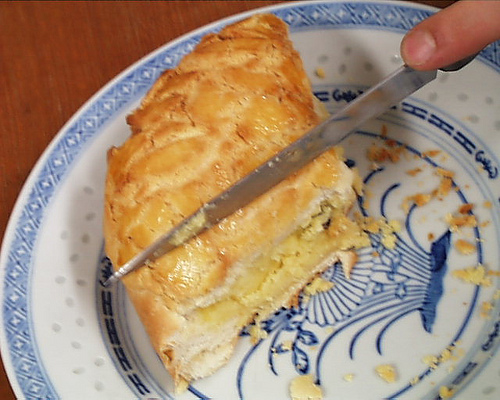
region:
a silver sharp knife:
[107, 49, 441, 294]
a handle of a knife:
[436, 41, 482, 78]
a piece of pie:
[98, 27, 373, 397]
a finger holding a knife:
[403, 2, 498, 74]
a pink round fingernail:
[400, 28, 434, 61]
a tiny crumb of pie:
[372, 361, 399, 382]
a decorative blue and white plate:
[4, 4, 491, 398]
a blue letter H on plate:
[112, 346, 132, 371]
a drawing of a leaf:
[291, 345, 312, 374]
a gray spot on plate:
[61, 293, 76, 308]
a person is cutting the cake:
[86, 3, 493, 354]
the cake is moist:
[78, 59, 393, 344]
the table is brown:
[0, 1, 325, 158]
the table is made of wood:
[3, 1, 388, 182]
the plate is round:
[1, 1, 493, 377]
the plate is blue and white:
[3, 7, 459, 385]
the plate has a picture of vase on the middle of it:
[191, 168, 490, 396]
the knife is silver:
[58, 71, 479, 223]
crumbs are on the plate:
[348, 136, 497, 285]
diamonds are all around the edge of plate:
[0, 114, 121, 379]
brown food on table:
[93, 20, 347, 336]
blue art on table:
[370, 216, 467, 344]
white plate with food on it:
[62, 213, 92, 273]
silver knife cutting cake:
[90, 66, 422, 299]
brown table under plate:
[0, 27, 90, 74]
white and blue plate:
[421, 111, 488, 274]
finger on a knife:
[391, 3, 491, 79]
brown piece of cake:
[91, 0, 401, 368]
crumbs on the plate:
[391, 158, 478, 302]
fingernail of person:
[367, 23, 439, 108]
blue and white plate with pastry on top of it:
[6, 12, 494, 390]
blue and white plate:
[7, 50, 476, 385]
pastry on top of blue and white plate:
[99, 45, 372, 379]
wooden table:
[8, 52, 107, 88]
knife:
[87, 49, 482, 311]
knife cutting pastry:
[92, 49, 494, 290]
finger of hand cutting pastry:
[399, 42, 498, 79]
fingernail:
[398, 26, 443, 66]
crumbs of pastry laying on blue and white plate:
[370, 122, 490, 289]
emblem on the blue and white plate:
[203, 164, 473, 371]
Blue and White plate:
[13, 7, 492, 375]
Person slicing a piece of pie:
[133, 15, 496, 206]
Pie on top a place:
[136, 16, 358, 375]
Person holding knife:
[86, 16, 484, 308]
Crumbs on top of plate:
[365, 127, 497, 340]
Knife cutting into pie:
[83, 117, 416, 343]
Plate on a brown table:
[11, 12, 214, 232]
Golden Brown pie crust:
[100, 50, 362, 305]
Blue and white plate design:
[370, 172, 494, 397]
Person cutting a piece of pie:
[88, 0, 475, 346]